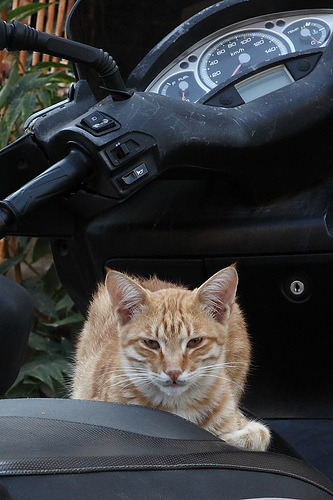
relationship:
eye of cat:
[138, 338, 162, 354] [75, 271, 303, 454]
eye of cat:
[184, 334, 204, 351] [75, 271, 303, 454]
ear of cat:
[103, 268, 152, 319] [75, 271, 303, 454]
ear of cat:
[196, 262, 243, 316] [75, 271, 303, 454]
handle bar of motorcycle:
[0, 37, 332, 234] [8, 13, 332, 499]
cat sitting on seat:
[75, 271, 303, 454] [6, 393, 283, 478]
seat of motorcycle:
[6, 393, 283, 478] [8, 13, 332, 499]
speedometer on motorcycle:
[195, 28, 302, 92] [8, 13, 332, 499]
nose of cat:
[163, 368, 184, 386] [75, 271, 303, 454]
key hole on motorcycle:
[282, 278, 310, 299] [8, 13, 332, 499]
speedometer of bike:
[195, 28, 302, 92] [8, 13, 332, 499]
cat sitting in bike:
[75, 271, 303, 454] [8, 13, 332, 499]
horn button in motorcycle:
[116, 159, 149, 189] [8, 13, 332, 499]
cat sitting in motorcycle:
[75, 271, 303, 454] [8, 13, 332, 499]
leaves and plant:
[1, 55, 72, 123] [2, 7, 78, 397]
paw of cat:
[219, 423, 271, 454] [75, 271, 303, 454]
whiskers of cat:
[104, 369, 159, 394] [75, 271, 303, 454]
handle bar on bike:
[0, 37, 332, 234] [8, 13, 332, 499]